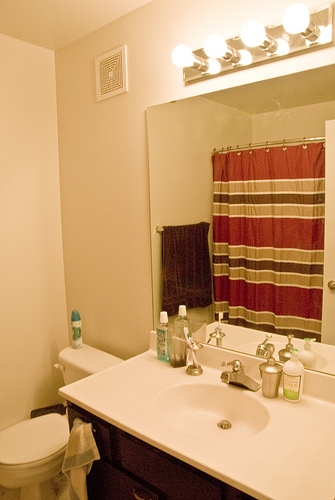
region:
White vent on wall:
[77, 37, 145, 104]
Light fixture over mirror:
[167, 0, 333, 89]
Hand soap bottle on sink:
[280, 345, 306, 406]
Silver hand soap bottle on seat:
[257, 343, 283, 402]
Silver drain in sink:
[210, 407, 232, 432]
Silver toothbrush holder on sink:
[183, 341, 205, 377]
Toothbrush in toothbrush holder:
[180, 325, 202, 368]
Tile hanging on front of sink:
[57, 407, 104, 497]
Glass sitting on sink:
[163, 324, 192, 369]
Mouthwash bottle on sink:
[151, 307, 177, 376]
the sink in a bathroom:
[140, 375, 272, 450]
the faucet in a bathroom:
[217, 353, 261, 391]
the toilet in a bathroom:
[0, 395, 67, 498]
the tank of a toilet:
[44, 342, 126, 387]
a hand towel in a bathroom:
[58, 413, 103, 495]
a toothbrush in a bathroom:
[182, 323, 199, 366]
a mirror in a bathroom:
[136, 95, 322, 334]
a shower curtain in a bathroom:
[206, 142, 331, 334]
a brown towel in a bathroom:
[155, 220, 217, 320]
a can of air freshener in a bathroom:
[66, 305, 83, 351]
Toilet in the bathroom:
[2, 340, 129, 497]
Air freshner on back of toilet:
[69, 306, 80, 347]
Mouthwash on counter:
[156, 310, 166, 360]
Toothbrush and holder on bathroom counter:
[183, 324, 201, 372]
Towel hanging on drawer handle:
[61, 415, 98, 497]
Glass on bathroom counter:
[167, 325, 183, 364]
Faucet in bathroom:
[217, 353, 257, 391]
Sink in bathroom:
[149, 375, 273, 448]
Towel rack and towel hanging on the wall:
[154, 224, 221, 315]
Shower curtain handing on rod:
[210, 148, 319, 339]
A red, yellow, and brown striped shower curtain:
[210, 142, 326, 337]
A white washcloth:
[60, 414, 90, 493]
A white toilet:
[0, 398, 69, 491]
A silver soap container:
[257, 339, 276, 394]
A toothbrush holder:
[176, 324, 199, 371]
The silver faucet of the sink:
[218, 354, 258, 387]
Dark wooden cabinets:
[69, 408, 225, 495]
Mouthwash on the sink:
[154, 307, 169, 358]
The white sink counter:
[60, 348, 329, 491]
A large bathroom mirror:
[149, 99, 332, 359]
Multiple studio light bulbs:
[171, 3, 330, 79]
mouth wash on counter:
[152, 306, 172, 362]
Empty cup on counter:
[163, 324, 187, 365]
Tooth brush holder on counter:
[181, 323, 205, 378]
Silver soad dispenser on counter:
[256, 348, 282, 398]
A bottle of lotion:
[279, 346, 307, 403]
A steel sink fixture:
[219, 357, 260, 393]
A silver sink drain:
[216, 416, 232, 429]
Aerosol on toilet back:
[68, 305, 84, 353]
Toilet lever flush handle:
[54, 361, 64, 370]